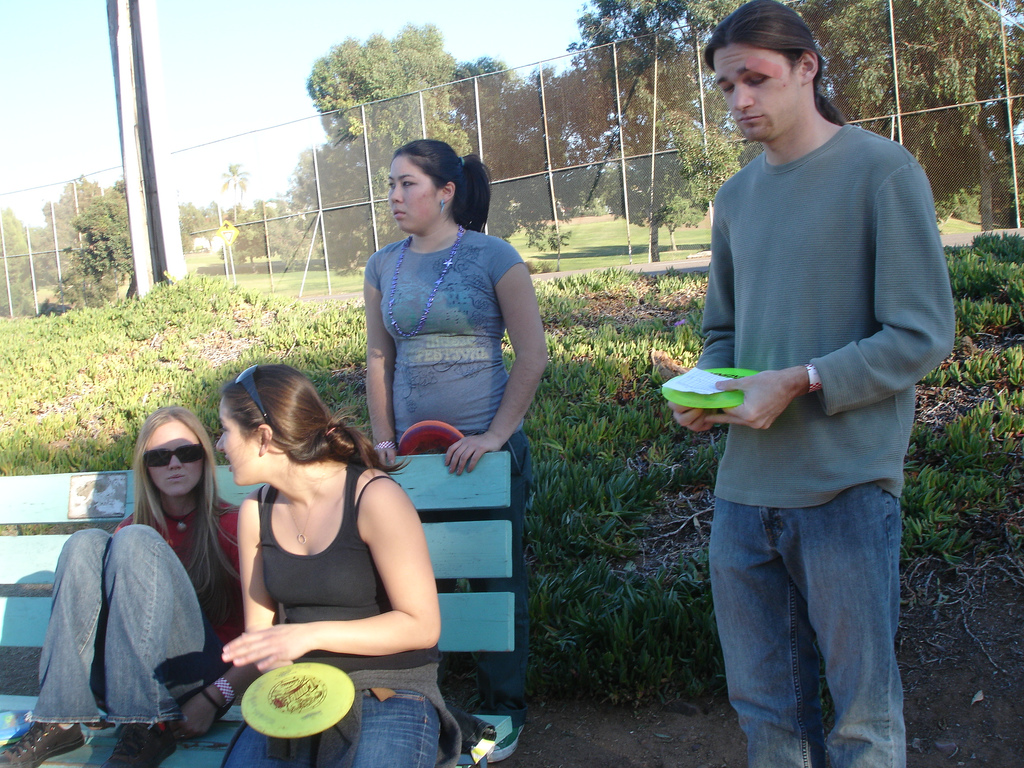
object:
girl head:
[131, 410, 219, 523]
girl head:
[214, 364, 331, 486]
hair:
[392, 139, 491, 234]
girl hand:
[444, 432, 501, 475]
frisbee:
[241, 662, 354, 740]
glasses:
[143, 444, 201, 466]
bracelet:
[805, 362, 822, 394]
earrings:
[440, 197, 446, 212]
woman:
[2, 405, 240, 767]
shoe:
[106, 718, 182, 766]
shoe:
[2, 716, 89, 767]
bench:
[0, 447, 517, 765]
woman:
[362, 137, 543, 763]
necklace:
[386, 224, 465, 336]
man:
[666, 0, 957, 766]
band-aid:
[744, 56, 783, 80]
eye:
[748, 73, 768, 85]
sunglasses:
[233, 364, 277, 435]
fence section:
[611, 22, 706, 160]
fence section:
[550, 158, 630, 271]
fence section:
[781, 0, 901, 124]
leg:
[781, 482, 905, 766]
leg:
[707, 496, 816, 767]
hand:
[704, 369, 794, 430]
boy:
[666, 0, 957, 766]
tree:
[54, 188, 134, 310]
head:
[388, 139, 492, 232]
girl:
[217, 366, 444, 768]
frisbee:
[662, 367, 763, 408]